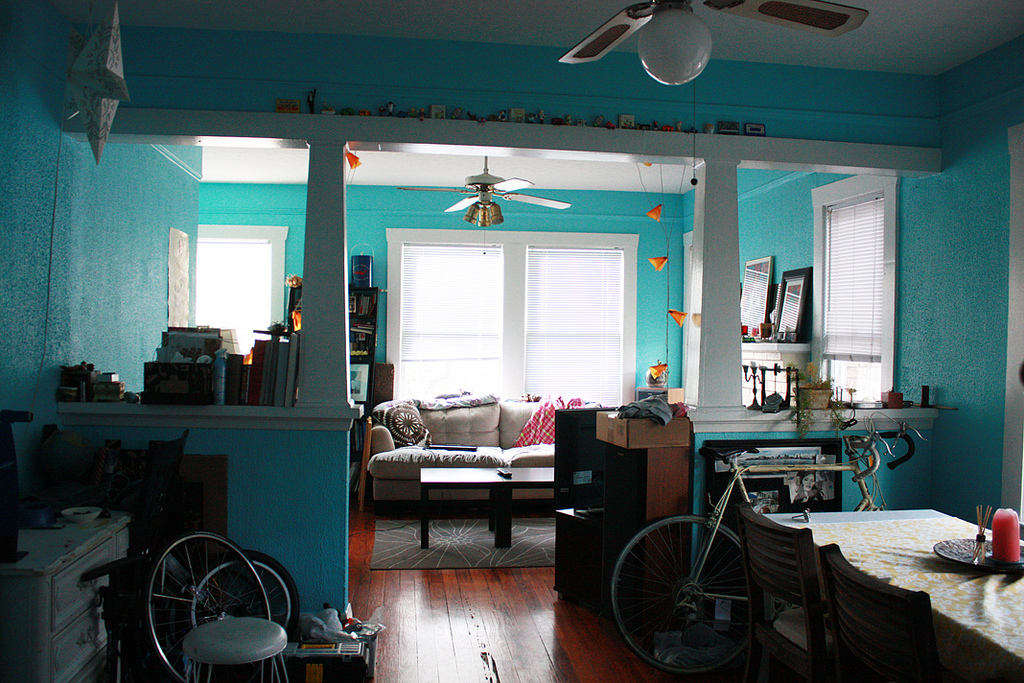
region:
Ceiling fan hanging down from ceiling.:
[603, 9, 867, 74]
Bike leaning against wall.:
[642, 445, 912, 646]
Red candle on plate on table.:
[986, 497, 1022, 574]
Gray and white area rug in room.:
[364, 503, 574, 573]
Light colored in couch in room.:
[373, 373, 586, 479]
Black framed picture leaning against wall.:
[767, 253, 812, 364]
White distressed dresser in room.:
[19, 515, 143, 672]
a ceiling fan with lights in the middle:
[382, 149, 588, 244]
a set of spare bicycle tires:
[139, 518, 313, 680]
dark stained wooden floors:
[407, 579, 529, 677]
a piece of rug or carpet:
[366, 508, 611, 589]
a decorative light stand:
[625, 158, 702, 427]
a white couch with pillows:
[362, 385, 572, 515]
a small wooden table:
[410, 458, 579, 547]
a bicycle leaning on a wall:
[593, 417, 916, 678]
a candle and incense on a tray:
[932, 496, 1022, 577]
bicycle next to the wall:
[606, 409, 921, 660]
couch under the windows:
[385, 393, 563, 508]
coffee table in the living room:
[421, 455, 548, 551]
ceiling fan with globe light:
[549, 3, 864, 111]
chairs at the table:
[746, 493, 924, 680]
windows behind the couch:
[378, 221, 639, 398]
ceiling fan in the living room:
[423, 172, 560, 231]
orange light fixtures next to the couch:
[639, 194, 691, 390]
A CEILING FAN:
[390, 151, 580, 234]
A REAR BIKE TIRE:
[603, 508, 760, 677]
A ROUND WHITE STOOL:
[176, 609, 295, 674]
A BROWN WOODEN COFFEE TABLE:
[413, 461, 556, 548]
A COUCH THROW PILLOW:
[372, 395, 433, 453]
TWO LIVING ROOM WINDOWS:
[379, 221, 646, 409]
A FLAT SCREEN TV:
[549, 402, 611, 517]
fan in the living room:
[420, 160, 576, 240]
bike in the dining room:
[600, 411, 927, 677]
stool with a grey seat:
[171, 613, 288, 680]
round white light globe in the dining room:
[637, 12, 723, 93]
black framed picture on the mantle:
[768, 263, 816, 344]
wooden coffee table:
[407, 455, 594, 551]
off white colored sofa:
[364, 379, 636, 510]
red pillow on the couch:
[508, 391, 591, 455]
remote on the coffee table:
[490, 458, 516, 485]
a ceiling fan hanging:
[465, 142, 517, 209]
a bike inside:
[593, 434, 903, 609]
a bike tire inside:
[596, 513, 821, 670]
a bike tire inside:
[119, 525, 227, 680]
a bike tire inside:
[260, 516, 368, 638]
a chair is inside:
[128, 572, 306, 671]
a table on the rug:
[365, 461, 590, 583]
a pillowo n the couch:
[424, 396, 467, 442]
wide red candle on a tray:
[987, 507, 1020, 562]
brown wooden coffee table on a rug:
[413, 460, 563, 550]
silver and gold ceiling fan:
[392, 170, 573, 231]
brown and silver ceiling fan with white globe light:
[556, 6, 870, 83]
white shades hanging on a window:
[391, 240, 505, 406]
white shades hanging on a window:
[518, 245, 629, 407]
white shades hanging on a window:
[195, 226, 284, 362]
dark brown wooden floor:
[263, 504, 832, 679]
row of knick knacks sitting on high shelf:
[263, 84, 764, 148]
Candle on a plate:
[986, 508, 1019, 559]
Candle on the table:
[985, 493, 1020, 560]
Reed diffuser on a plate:
[963, 508, 992, 556]